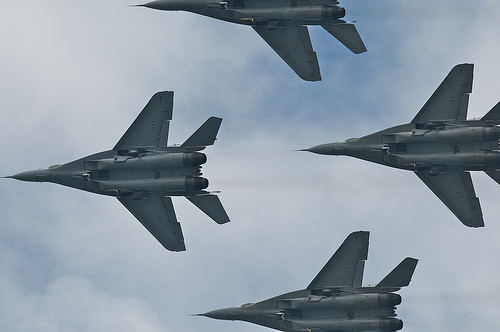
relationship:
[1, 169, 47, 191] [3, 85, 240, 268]
nose of jet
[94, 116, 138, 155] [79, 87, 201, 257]
edges of wings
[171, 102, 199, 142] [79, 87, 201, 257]
space between wings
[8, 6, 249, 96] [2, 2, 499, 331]
clouds in sky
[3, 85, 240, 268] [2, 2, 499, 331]
jet in sky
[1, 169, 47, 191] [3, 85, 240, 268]
head of jet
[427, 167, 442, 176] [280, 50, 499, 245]
wheel on jet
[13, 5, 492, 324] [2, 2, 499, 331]
airplanes in sky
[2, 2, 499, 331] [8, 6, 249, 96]
sky with clouds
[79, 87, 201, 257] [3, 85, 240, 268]
wings on airplane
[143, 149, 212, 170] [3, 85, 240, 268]
engine on jet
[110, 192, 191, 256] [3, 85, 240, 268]
wing on jet